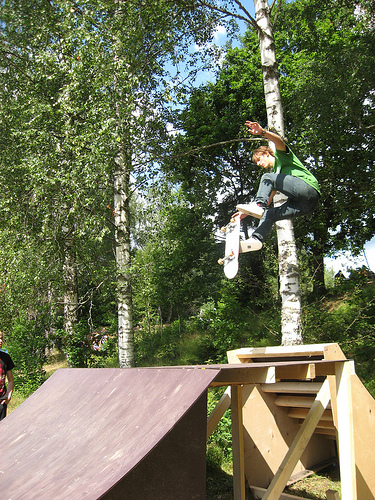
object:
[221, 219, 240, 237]
two wheels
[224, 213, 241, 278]
skateboard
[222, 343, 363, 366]
stairs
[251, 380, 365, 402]
stairs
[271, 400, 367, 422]
stairs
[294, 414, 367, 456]
stairs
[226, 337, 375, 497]
wood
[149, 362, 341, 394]
platform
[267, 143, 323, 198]
green shirt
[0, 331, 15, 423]
boy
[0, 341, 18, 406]
t-shirt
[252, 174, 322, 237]
jeans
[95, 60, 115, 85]
leaves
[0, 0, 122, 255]
leaves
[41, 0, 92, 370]
birch tree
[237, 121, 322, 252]
skateboarder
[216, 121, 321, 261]
man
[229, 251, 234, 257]
wheels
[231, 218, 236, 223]
wheels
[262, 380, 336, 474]
steps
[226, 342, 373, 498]
ramp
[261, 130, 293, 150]
arm